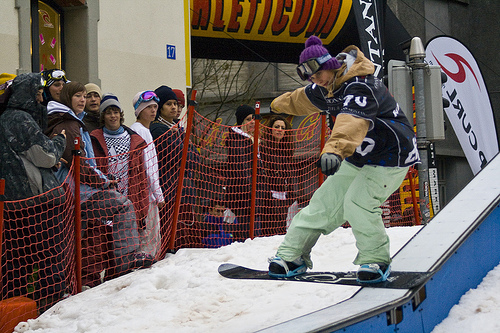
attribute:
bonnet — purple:
[291, 32, 340, 82]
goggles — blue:
[296, 52, 331, 82]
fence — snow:
[7, 90, 418, 300]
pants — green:
[268, 156, 392, 270]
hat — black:
[236, 104, 253, 129]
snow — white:
[12, 227, 498, 332]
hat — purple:
[296, 35, 340, 68]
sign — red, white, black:
[196, 2, 342, 37]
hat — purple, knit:
[299, 34, 339, 72]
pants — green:
[271, 166, 411, 266]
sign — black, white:
[357, 0, 386, 66]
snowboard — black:
[193, 218, 463, 303]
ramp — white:
[256, 148, 499, 330]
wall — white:
[7, 9, 253, 228]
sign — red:
[178, 1, 355, 48]